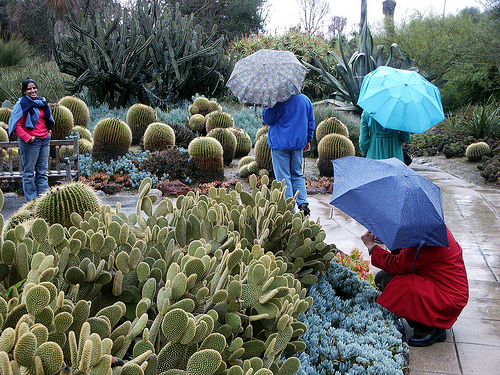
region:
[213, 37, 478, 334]
people with umbrellas in hand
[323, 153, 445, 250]
umbrella with woman with red jacket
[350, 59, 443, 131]
light blue umbrella with person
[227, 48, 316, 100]
umbrella with person with pants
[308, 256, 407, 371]
light blue flowers on ground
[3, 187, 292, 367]
group of cacti on ground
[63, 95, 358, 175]
dome shaped cacti in garden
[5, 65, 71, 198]
woman near dome shaped cacti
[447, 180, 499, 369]
sidewalk area of garden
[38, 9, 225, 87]
bush of miscellaneous plant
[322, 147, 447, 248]
Blue umbrella over person.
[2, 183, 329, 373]
Cactus in the forefront.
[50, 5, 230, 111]
Large dark catcus in the background.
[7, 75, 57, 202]
Red shirt on the woman.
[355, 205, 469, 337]
Red coat on person.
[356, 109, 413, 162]
Aqua colored coat on person.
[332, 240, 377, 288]
Pink flowers by cactus.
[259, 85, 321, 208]
Person wearing blue jacket.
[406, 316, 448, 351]
Black shoe on foot.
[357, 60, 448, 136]
Aqua colored umbrella.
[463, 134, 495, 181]
Small cactus in a graden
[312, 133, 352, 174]
Small cactus in a graden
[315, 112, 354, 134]
Small cactus in a graden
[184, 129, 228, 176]
Small cactus in a graden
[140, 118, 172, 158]
Small cactus in a graden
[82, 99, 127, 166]
Small cactus in a graden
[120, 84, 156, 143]
Small cactus in a graden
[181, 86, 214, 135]
Small cactus in a graden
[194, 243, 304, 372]
Small cactus in a graden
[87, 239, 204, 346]
Small cactus in a graden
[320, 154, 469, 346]
Individual crouching to look at foliage under and umbrella.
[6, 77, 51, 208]
Dark haired woman smiling.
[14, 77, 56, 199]
Woman smiling among large cacti.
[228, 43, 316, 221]
Individual looking at large collection of cactus.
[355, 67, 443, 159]
Woman looking at cactus while holding an umbrella.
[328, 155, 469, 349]
Woman in red jacket crouching down to look at cactus.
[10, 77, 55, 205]
Dark haired woman smiling outdoors.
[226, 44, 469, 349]
Several people enjoying the sight of large cactus.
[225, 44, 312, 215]
Person holding an umbrella while looking at plant life.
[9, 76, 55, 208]
Woman smiling while watching a friend.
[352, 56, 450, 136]
A light turquoise umbrella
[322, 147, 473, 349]
A woman in a red coat crouching with a blue umbrella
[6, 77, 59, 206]
A woman beaming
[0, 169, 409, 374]
A lush cactus garden bed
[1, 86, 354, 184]
Large globelike cacti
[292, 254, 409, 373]
A collection of greyish succulents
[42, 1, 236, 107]
A tall cluster of slender cactus branches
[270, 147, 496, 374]
A rainy, square-stoned pathway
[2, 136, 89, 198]
A sparse wooden bench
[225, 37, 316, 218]
A person dressed all in blue